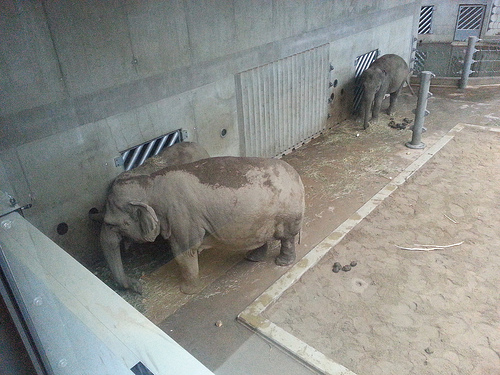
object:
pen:
[2, 7, 485, 367]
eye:
[108, 223, 115, 229]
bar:
[120, 128, 180, 173]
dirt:
[260, 126, 499, 373]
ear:
[129, 201, 160, 243]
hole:
[220, 128, 228, 137]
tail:
[297, 229, 301, 244]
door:
[234, 43, 330, 160]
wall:
[0, 0, 499, 267]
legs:
[167, 228, 205, 294]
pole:
[404, 71, 435, 149]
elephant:
[361, 54, 415, 130]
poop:
[387, 117, 412, 130]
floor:
[80, 84, 500, 375]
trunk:
[363, 91, 374, 129]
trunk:
[100, 223, 141, 294]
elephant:
[97, 156, 304, 294]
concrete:
[326, 138, 441, 248]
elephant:
[89, 141, 210, 225]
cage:
[51, 74, 454, 296]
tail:
[405, 79, 414, 95]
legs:
[276, 235, 296, 266]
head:
[362, 67, 386, 129]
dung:
[332, 260, 356, 273]